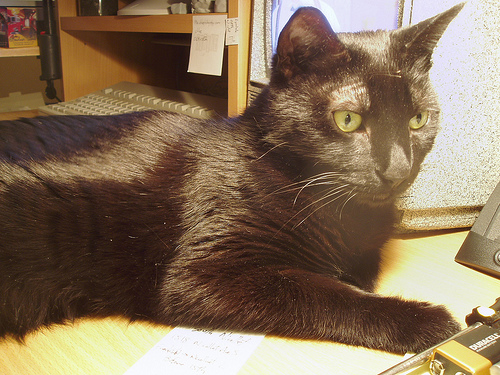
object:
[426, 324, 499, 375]
battery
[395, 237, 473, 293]
table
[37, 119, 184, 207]
fur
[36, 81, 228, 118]
keyboard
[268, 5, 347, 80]
ear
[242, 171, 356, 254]
whisker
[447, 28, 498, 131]
light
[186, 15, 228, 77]
paper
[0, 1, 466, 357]
cat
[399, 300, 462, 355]
paw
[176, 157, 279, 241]
spot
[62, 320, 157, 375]
desk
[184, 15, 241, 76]
post-it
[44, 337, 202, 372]
surface